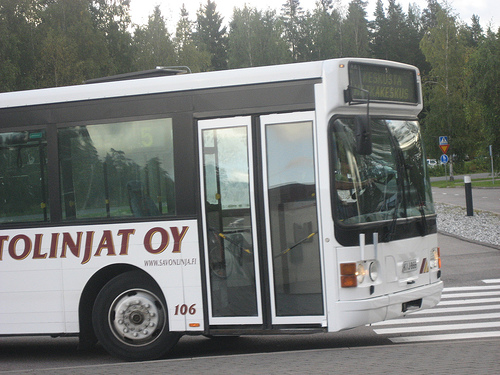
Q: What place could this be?
A: It is a road.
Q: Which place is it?
A: It is a road.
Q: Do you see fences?
A: No, there are no fences.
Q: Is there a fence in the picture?
A: No, there are no fences.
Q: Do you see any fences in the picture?
A: No, there are no fences.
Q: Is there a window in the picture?
A: Yes, there are windows.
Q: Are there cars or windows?
A: Yes, there are windows.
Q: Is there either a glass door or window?
A: Yes, there are glass windows.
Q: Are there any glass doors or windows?
A: Yes, there are glass windows.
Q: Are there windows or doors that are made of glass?
A: Yes, the windows are made of glass.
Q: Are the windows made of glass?
A: Yes, the windows are made of glass.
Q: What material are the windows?
A: The windows are made of glass.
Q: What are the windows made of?
A: The windows are made of glass.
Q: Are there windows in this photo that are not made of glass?
A: No, there are windows but they are made of glass.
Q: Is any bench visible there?
A: No, there are no benches.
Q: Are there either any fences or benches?
A: No, there are no benches or fences.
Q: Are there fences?
A: No, there are no fences.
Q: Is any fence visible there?
A: No, there are no fences.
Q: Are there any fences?
A: No, there are no fences.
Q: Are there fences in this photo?
A: No, there are no fences.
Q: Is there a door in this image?
A: Yes, there is a door.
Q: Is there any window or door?
A: Yes, there is a door.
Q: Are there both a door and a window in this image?
A: Yes, there are both a door and a window.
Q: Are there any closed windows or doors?
A: Yes, there is a closed door.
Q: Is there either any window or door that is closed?
A: Yes, the door is closed.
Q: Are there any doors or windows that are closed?
A: Yes, the door is closed.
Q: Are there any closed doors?
A: Yes, there is a closed door.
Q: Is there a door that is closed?
A: Yes, there is a door that is closed.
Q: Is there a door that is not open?
A: Yes, there is an closed door.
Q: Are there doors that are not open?
A: Yes, there is an closed door.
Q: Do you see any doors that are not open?
A: Yes, there is an closed door.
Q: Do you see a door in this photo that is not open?
A: Yes, there is an closed door.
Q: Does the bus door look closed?
A: Yes, the door is closed.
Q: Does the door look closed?
A: Yes, the door is closed.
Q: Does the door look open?
A: No, the door is closed.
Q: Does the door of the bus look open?
A: No, the door is closed.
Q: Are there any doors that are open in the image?
A: No, there is a door but it is closed.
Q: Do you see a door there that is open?
A: No, there is a door but it is closed.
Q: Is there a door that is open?
A: No, there is a door but it is closed.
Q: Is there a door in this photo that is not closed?
A: No, there is a door but it is closed.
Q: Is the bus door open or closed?
A: The door is closed.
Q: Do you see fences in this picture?
A: No, there are no fences.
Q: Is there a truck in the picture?
A: No, there are no trucks.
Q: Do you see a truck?
A: No, there are no trucks.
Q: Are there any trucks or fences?
A: No, there are no trucks or fences.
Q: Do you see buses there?
A: Yes, there is a bus.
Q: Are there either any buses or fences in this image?
A: Yes, there is a bus.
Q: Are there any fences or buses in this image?
A: Yes, there is a bus.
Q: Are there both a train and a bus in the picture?
A: No, there is a bus but no trains.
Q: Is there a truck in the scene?
A: No, there are no trucks.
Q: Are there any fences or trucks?
A: No, there are no trucks or fences.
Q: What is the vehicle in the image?
A: The vehicle is a bus.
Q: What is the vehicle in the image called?
A: The vehicle is a bus.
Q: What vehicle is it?
A: The vehicle is a bus.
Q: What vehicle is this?
A: That is a bus.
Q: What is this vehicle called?
A: That is a bus.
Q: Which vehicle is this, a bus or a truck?
A: That is a bus.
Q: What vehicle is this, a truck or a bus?
A: That is a bus.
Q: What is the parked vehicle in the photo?
A: The vehicle is a bus.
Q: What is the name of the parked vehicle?
A: The vehicle is a bus.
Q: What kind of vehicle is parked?
A: The vehicle is a bus.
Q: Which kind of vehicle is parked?
A: The vehicle is a bus.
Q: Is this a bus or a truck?
A: This is a bus.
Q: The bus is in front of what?
A: The bus is in front of the trees.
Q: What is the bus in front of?
A: The bus is in front of the trees.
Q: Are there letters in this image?
A: Yes, there are letters.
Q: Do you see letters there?
A: Yes, there are letters.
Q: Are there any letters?
A: Yes, there are letters.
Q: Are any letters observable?
A: Yes, there are letters.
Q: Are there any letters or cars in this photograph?
A: Yes, there are letters.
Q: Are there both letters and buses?
A: Yes, there are both letters and a bus.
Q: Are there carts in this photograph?
A: No, there are no carts.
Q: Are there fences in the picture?
A: No, there are no fences.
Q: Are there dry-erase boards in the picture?
A: No, there are no dry-erase boards.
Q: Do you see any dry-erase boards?
A: No, there are no dry-erase boards.